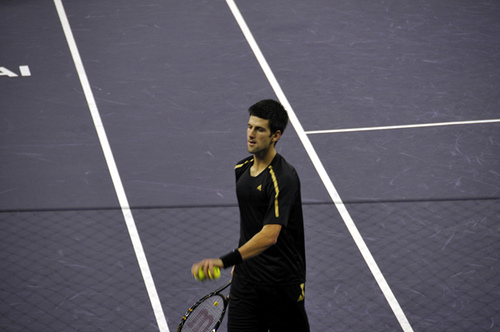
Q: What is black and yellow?
A: The shirt.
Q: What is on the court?
A: White lines.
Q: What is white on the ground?
A: Lines.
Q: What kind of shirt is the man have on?
A: Tshirt.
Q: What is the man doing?
A: Playing tennis.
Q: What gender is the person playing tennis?
A: Male.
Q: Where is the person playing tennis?
A: Tennis court.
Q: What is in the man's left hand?
A: Tennis balls.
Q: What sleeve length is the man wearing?
A: Short-sleeved.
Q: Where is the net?
A: Behind the athlete.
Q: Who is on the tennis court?
A: Tennis player.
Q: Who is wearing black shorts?
A: Tennis player.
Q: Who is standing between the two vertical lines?
A: Tennis player.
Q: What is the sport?
A: Tennis.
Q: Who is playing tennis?
A: A man.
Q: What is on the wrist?
A: A wristband.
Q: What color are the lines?
A: White.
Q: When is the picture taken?
A: Daytime.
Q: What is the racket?
A: A tennis racket.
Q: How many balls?
A: Two.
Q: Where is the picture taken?
A: Tennis court.